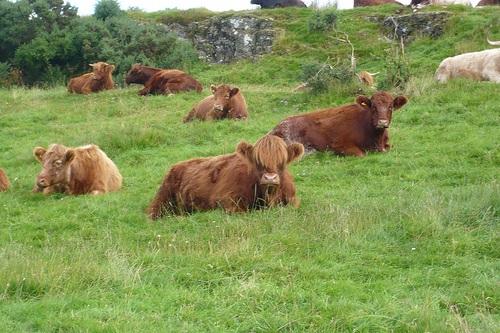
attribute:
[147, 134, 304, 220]
cow — lying, brown, looking, big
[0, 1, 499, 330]
grass — green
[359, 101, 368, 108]
tag — yellow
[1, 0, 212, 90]
bushes — green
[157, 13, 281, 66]
rock — grey, white, large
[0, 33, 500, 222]
animals — relaxing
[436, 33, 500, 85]
cow — white